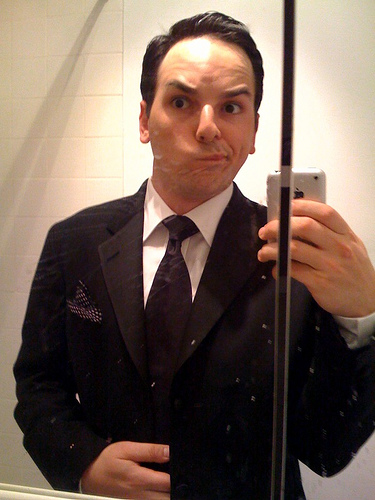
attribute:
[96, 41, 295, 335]
man — smiling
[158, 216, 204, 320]
tie — black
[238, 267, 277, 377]
mirror — dirty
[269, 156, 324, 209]
phone — silver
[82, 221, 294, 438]
suit — black, dark